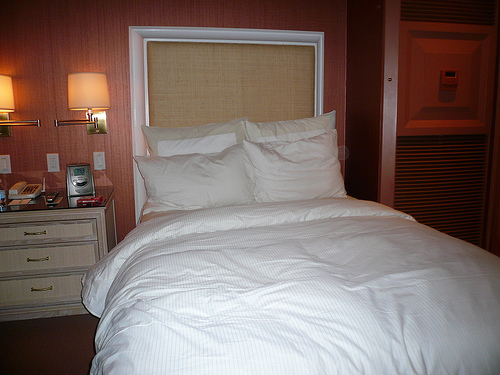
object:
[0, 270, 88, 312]
drawers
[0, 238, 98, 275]
drawers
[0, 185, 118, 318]
desk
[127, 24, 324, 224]
window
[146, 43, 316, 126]
shade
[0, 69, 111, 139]
two lamps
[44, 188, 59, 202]
remote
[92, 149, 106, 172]
light switch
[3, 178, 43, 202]
telephone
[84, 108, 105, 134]
fire hydrant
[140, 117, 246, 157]
pillows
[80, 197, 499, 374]
comforter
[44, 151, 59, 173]
socket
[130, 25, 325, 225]
headboard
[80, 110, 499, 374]
bed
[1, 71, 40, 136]
lamp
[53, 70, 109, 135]
lamp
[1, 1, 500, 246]
wall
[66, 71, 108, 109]
lamp shade